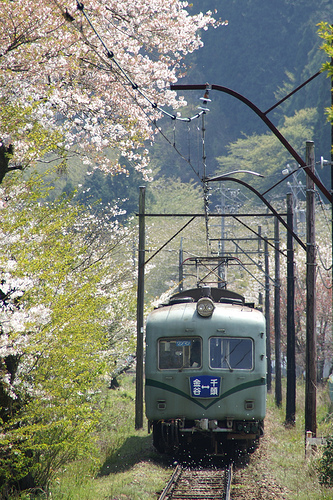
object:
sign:
[190, 374, 222, 397]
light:
[247, 401, 253, 408]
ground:
[181, 0, 333, 113]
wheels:
[153, 435, 259, 463]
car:
[145, 287, 266, 462]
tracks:
[157, 459, 233, 500]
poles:
[163, 79, 332, 204]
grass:
[95, 414, 145, 499]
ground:
[116, 453, 304, 497]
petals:
[168, 433, 255, 473]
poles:
[135, 186, 145, 429]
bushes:
[0, 162, 129, 499]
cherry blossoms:
[1, 0, 223, 405]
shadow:
[93, 432, 153, 480]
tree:
[241, 236, 333, 388]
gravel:
[160, 457, 282, 500]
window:
[209, 336, 253, 369]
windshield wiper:
[223, 355, 233, 371]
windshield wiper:
[178, 356, 193, 373]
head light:
[158, 401, 165, 409]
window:
[158, 337, 202, 369]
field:
[0, 328, 333, 500]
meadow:
[103, 391, 333, 500]